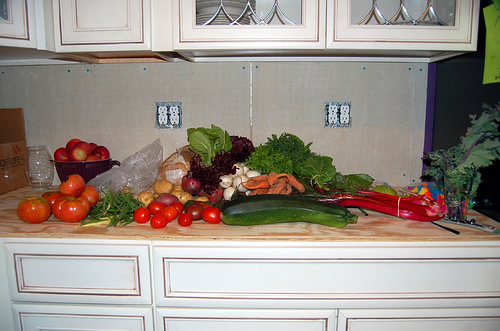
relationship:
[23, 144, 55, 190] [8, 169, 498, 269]
glass on counter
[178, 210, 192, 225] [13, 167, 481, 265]
vegetable on counter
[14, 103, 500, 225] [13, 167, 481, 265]
vegetable on counter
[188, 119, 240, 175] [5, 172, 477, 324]
spinach in bunches on table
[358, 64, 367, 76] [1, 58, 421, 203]
nail hole in wall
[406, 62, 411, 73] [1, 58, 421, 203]
nail hole in wall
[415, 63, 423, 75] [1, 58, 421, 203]
nail hole in wall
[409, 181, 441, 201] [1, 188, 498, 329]
balloons on table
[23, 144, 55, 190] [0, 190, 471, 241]
glass on table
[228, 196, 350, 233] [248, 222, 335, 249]
cucumber on counter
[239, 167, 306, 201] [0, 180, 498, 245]
carrots stacked on counter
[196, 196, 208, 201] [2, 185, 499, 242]
potatoes on counter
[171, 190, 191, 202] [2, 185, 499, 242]
potatoes on counter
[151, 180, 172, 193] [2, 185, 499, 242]
potatoes on counter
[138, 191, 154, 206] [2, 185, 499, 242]
potatoes on counter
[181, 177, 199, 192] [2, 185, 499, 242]
potatoes on counter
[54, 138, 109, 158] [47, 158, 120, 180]
apples in purple jar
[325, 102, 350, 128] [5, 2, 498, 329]
outlet in wall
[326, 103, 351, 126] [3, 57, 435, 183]
outlet in wall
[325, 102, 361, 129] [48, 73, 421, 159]
outlet in wall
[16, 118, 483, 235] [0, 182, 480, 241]
food on counter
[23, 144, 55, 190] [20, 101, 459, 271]
glass on counter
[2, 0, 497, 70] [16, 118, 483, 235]
cabinets above food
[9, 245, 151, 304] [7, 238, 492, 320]
drawer under counter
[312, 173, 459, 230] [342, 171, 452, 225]
radishes in bunch